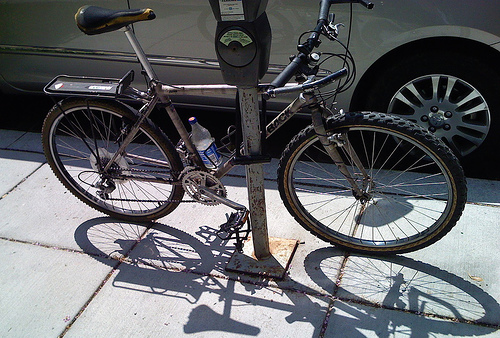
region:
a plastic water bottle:
[186, 114, 227, 172]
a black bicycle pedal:
[213, 207, 255, 253]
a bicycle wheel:
[273, 106, 469, 263]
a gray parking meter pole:
[236, 84, 276, 265]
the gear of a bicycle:
[180, 163, 231, 207]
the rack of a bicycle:
[40, 62, 142, 98]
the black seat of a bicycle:
[71, 1, 158, 39]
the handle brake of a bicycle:
[326, 12, 352, 38]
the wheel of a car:
[355, 42, 499, 177]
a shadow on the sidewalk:
[69, 210, 499, 335]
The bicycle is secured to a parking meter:
[37, 4, 473, 285]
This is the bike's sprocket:
[175, 162, 231, 215]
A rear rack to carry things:
[36, 57, 146, 122]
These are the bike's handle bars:
[264, 2, 364, 97]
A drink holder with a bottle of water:
[183, 111, 232, 172]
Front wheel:
[279, 107, 466, 259]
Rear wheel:
[37, 94, 183, 221]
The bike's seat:
[71, 2, 181, 64]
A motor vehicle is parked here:
[377, 10, 498, 120]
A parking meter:
[202, 0, 281, 91]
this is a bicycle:
[52, 65, 451, 248]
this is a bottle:
[191, 115, 211, 155]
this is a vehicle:
[385, 5, 492, 82]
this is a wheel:
[401, 49, 493, 74]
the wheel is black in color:
[437, 55, 459, 62]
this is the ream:
[411, 83, 470, 108]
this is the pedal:
[204, 200, 249, 235]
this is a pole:
[249, 166, 270, 246]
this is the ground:
[18, 227, 186, 327]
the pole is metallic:
[249, 180, 264, 238]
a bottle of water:
[183, 113, 224, 169]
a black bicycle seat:
[70, 2, 157, 37]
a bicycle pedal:
[218, 207, 255, 248]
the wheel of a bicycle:
[274, 105, 471, 262]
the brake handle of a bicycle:
[323, 7, 347, 33]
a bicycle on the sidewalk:
[31, 0, 471, 263]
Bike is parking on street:
[36, 1, 478, 263]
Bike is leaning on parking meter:
[40, 3, 475, 258]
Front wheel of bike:
[276, 104, 468, 261]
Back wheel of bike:
[33, 91, 189, 227]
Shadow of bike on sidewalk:
[59, 218, 497, 332]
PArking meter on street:
[205, 0, 298, 280]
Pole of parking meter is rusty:
[211, 86, 306, 286]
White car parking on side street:
[6, 3, 497, 168]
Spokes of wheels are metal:
[311, 136, 432, 234]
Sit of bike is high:
[71, 1, 166, 44]